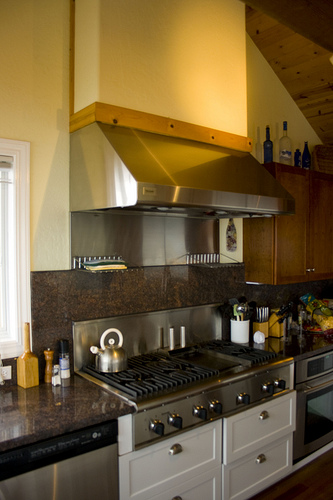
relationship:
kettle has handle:
[89, 326, 128, 374] [97, 322, 127, 351]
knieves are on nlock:
[277, 297, 296, 324] [267, 307, 287, 340]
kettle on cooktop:
[89, 326, 128, 374] [70, 295, 296, 441]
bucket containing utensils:
[230, 318, 251, 345] [232, 298, 253, 322]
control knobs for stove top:
[151, 371, 293, 438] [86, 341, 279, 396]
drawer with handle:
[223, 388, 301, 469] [259, 409, 268, 420]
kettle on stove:
[89, 326, 128, 374] [74, 331, 287, 400]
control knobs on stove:
[151, 377, 291, 439] [74, 326, 302, 445]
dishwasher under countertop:
[1, 418, 121, 498] [1, 368, 136, 452]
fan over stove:
[70, 125, 301, 225] [68, 301, 296, 448]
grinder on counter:
[43, 344, 52, 386] [0, 371, 137, 456]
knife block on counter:
[250, 304, 297, 334] [234, 325, 330, 363]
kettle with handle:
[89, 326, 128, 374] [96, 325, 122, 349]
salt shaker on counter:
[48, 360, 66, 387] [0, 371, 135, 444]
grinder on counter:
[43, 344, 54, 384] [0, 371, 135, 444]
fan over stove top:
[70, 125, 296, 227] [67, 300, 293, 393]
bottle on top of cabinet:
[263, 125, 274, 165] [248, 159, 332, 284]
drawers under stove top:
[223, 389, 300, 470] [70, 288, 292, 413]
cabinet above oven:
[243, 159, 333, 286] [289, 351, 333, 479]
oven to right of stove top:
[289, 351, 332, 465] [77, 335, 296, 408]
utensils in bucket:
[232, 298, 253, 322] [230, 318, 251, 345]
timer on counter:
[249, 329, 268, 348] [256, 330, 329, 359]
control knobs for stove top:
[151, 377, 291, 439] [82, 331, 291, 401]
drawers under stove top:
[118, 389, 299, 497] [70, 334, 289, 404]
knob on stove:
[151, 420, 165, 435] [95, 322, 298, 497]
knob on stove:
[168, 414, 184, 429] [95, 322, 298, 497]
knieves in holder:
[277, 300, 296, 317] [265, 315, 288, 341]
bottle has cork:
[258, 118, 277, 164] [262, 121, 271, 130]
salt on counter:
[49, 362, 64, 385] [38, 376, 85, 409]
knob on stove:
[151, 420, 164, 434] [68, 301, 296, 448]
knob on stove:
[170, 414, 183, 427] [68, 301, 296, 448]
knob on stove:
[191, 406, 209, 419] [68, 301, 296, 448]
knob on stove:
[209, 400, 223, 413] [68, 301, 296, 448]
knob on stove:
[238, 391, 249, 404] [68, 301, 296, 448]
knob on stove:
[261, 382, 273, 394] [68, 301, 296, 448]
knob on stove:
[273, 376, 285, 388] [68, 301, 296, 448]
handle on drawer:
[167, 442, 180, 454] [118, 414, 222, 498]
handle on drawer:
[260, 409, 268, 419] [220, 389, 298, 465]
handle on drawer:
[255, 454, 267, 463] [219, 433, 294, 498]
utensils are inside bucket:
[232, 298, 253, 322] [225, 316, 258, 349]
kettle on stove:
[89, 326, 128, 374] [68, 301, 296, 448]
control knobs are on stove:
[151, 377, 291, 439] [68, 301, 296, 448]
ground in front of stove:
[264, 451, 329, 497] [72, 299, 300, 458]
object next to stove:
[16, 316, 42, 389] [68, 301, 296, 448]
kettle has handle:
[85, 321, 132, 374] [97, 322, 127, 351]